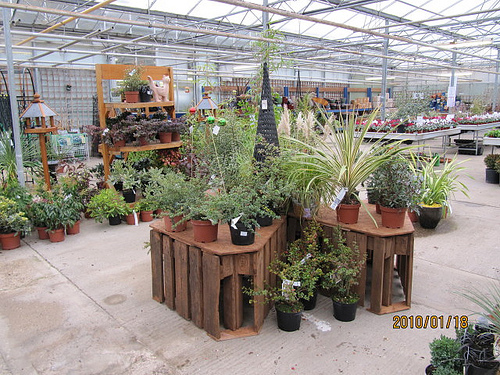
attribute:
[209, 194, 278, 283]
pot — clay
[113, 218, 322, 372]
stand — wood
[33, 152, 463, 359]
floor — gray , concrete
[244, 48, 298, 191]
cones — green 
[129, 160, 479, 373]
tables — wooden 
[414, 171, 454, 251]
pot — black , large 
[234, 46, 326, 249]
cone — black 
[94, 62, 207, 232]
shelves — wooden 